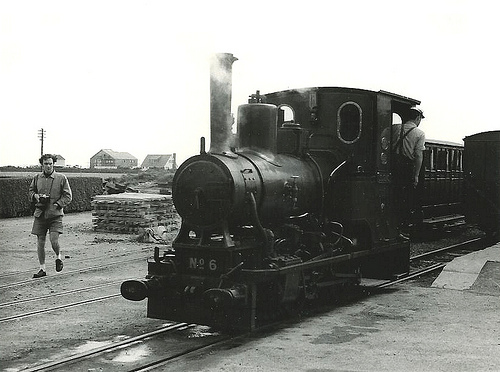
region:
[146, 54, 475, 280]
old black engine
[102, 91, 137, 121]
white clouds in blue sky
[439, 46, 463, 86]
white clouds in blue sky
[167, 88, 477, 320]
black train engine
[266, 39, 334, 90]
white clouds in blue sky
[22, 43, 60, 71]
white clouds in blue sky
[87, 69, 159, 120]
white clouds in blue sky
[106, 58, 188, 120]
white clouds in blue sky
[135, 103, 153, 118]
white clouds in blue sky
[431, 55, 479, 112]
white clouds in blue sky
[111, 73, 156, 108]
white clouds in blue sky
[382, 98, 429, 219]
man hanging out the train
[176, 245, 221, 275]
white letters on the train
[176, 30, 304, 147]
steam coming from the train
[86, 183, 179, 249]
stack of pallets on the ground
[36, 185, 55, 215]
man holding a camera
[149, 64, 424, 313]
train on the tracks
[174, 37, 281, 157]
steam coming from the train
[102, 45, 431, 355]
Black train engine on tracks.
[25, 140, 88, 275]
Man wearing coat and shorts.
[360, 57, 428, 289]
Train conductor leaning out of engine.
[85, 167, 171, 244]
Stack of wood near tracks.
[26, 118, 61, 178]
Electrical pole in background.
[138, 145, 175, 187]
White building that resembles a home.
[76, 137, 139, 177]
Large building resembling a business.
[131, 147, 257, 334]
Engine has number 6 painted on front.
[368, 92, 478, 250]
Black train passenger car.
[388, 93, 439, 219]
Train conductor wearing suspenders.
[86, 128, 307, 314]
front of the train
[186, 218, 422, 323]
bottom of the train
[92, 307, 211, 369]
track in front of train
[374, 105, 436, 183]
person in the train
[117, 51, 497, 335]
train is on track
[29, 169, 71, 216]
shirt is long sleeved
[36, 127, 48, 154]
electric pole is behind man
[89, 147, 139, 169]
building is in the distance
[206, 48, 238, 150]
train engine is blowing out smoke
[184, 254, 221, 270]
word is painted on front of train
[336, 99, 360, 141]
window is on the front of the train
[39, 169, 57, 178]
collar is around neck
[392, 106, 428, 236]
man is standing outside train